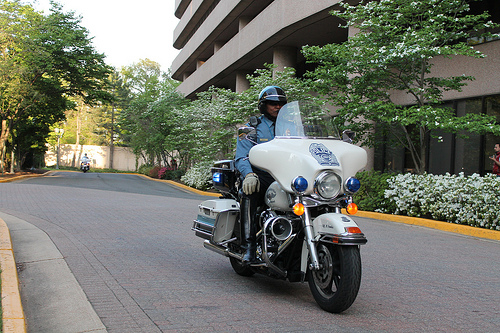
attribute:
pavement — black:
[37, 211, 145, 327]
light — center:
[314, 172, 342, 204]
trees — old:
[113, 2, 498, 173]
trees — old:
[0, 0, 145, 167]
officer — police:
[233, 84, 290, 268]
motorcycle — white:
[192, 99, 370, 315]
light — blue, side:
[333, 169, 355, 186]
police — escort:
[180, 50, 374, 297]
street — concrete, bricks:
[2, 166, 498, 331]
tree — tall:
[0, 0, 104, 172]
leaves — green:
[19, 42, 54, 100]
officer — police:
[230, 85, 315, 273]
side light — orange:
[290, 200, 307, 217]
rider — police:
[209, 127, 398, 312]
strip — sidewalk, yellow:
[382, 214, 498, 249]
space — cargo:
[186, 191, 250, 259]